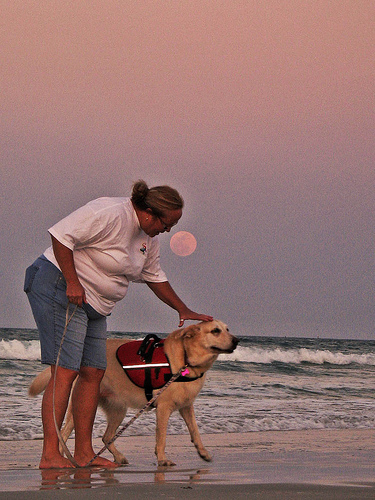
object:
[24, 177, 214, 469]
woman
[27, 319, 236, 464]
dog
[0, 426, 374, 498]
beach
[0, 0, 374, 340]
sky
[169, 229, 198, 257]
moon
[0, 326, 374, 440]
water